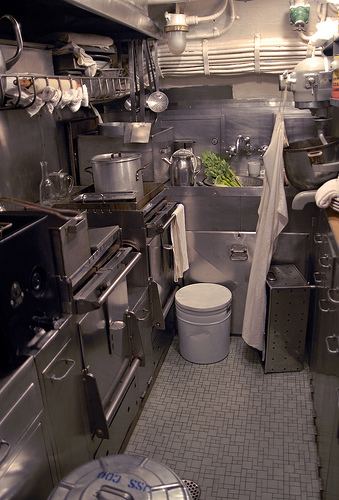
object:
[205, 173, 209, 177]
leaves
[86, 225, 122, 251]
table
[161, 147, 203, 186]
jug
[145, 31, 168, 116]
utensils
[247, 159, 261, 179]
cup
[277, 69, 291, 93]
mixer nozzle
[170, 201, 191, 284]
towel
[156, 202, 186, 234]
handle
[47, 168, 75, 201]
pitcher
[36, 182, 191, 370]
counter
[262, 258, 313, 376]
box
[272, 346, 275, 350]
holes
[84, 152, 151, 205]
pot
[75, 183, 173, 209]
stove top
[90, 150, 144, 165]
pot lid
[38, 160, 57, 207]
container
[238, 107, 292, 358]
apron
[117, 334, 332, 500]
linoleum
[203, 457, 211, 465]
tile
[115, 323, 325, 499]
floor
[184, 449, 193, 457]
tile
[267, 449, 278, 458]
white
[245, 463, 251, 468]
white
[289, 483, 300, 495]
white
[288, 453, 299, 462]
white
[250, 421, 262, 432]
white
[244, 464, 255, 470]
white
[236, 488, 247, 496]
white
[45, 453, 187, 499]
silver trashcan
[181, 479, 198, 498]
drain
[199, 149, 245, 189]
vegetables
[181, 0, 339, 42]
wall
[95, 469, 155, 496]
blue writing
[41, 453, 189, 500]
trashcan lid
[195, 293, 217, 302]
white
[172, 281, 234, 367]
container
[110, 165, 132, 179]
silver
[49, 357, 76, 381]
handle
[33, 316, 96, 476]
counter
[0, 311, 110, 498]
cabinet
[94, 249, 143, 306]
handle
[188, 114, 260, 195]
sink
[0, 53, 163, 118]
rack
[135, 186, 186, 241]
cabinets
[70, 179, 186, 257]
stove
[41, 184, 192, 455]
oven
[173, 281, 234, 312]
cover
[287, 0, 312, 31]
cover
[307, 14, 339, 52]
light